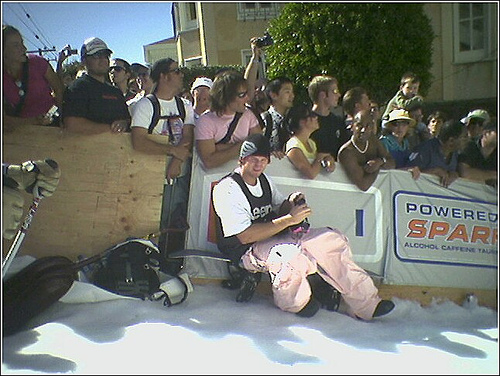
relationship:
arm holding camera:
[238, 31, 272, 101] [250, 30, 283, 46]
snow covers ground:
[2, 285, 497, 375] [72, 298, 487, 328]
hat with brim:
[81, 37, 106, 53] [88, 51, 124, 53]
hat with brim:
[197, 72, 212, 82] [179, 79, 216, 95]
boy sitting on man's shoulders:
[392, 68, 444, 149] [387, 123, 420, 163]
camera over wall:
[39, 103, 66, 124] [1, 116, 498, 309]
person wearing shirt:
[279, 100, 336, 179] [284, 133, 318, 163]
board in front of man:
[4, 122, 162, 269] [61, 37, 131, 134]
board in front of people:
[4, 122, 162, 269] [129, 57, 195, 185]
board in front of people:
[4, 122, 162, 269] [193, 69, 264, 169]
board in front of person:
[4, 122, 162, 269] [4, 22, 66, 120]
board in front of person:
[4, 122, 162, 269] [284, 105, 329, 171]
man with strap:
[194, 66, 266, 170] [214, 108, 243, 145]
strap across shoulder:
[214, 108, 243, 145] [237, 102, 257, 120]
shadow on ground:
[2, 282, 497, 374] [31, 302, 495, 352]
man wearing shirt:
[209, 132, 396, 320] [130, 87, 199, 152]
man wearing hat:
[209, 132, 396, 320] [236, 132, 271, 162]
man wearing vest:
[209, 132, 396, 320] [207, 172, 274, 255]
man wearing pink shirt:
[194, 68, 264, 170] [194, 107, 260, 152]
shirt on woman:
[282, 134, 321, 167] [280, 103, 337, 175]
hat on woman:
[371, 103, 419, 130] [371, 101, 448, 181]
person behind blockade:
[279, 100, 336, 179] [1, 127, 498, 307]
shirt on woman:
[279, 124, 327, 161] [270, 97, 339, 180]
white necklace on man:
[341, 134, 378, 157] [344, 114, 394, 198]